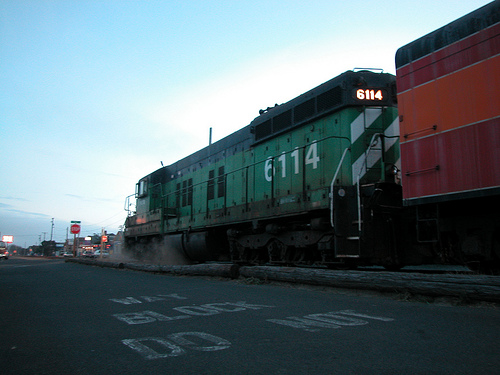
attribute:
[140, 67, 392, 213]
train — white, below, long, big, huge, green and white, close, here, green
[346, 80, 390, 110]
number — orange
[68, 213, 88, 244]
sign — red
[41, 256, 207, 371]
road — below, black, empty, here, close, paved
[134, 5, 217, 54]
sky — above, white, blue, light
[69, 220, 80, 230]
sign — red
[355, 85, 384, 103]
numbers — orange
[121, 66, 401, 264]
train — green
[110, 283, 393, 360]
paint — white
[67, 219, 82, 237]
sign — red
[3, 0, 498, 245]
sky — blue